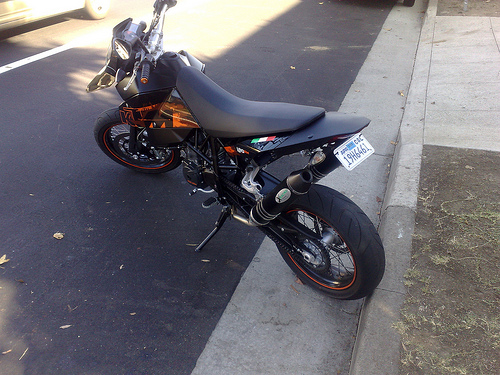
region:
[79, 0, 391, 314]
Motorcycle parked on the street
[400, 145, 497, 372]
Dead grass and dirt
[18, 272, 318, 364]
Concrete and asphalt street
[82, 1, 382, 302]
Motorcycle made by KTM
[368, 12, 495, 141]
Driveway entrance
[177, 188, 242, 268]
Motorcycle kickstand that's down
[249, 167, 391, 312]
Slick road tires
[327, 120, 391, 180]
Motorcycle license plate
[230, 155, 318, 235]
Muffler on the side of a motorcycle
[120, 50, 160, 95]
Clutch and hand grip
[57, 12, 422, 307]
the bike is black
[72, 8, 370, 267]
the bike is black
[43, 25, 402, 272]
the bike is black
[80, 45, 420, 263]
the bike is black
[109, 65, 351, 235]
the bike is black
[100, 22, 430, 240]
the bike is black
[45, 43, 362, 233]
the bike is black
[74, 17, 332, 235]
the bike is black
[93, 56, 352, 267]
the bike is black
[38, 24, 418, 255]
the bike is black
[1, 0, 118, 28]
car parked in background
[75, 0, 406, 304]
motorcycle parked on street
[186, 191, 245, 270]
kickstand is down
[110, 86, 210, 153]
design on bike is orange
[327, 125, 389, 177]
license plate 19h6461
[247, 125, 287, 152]
flag sticker is from Italy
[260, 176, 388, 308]
stripe on rim is orange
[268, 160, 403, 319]
tire is against curb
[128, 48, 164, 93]
handlebar tip is orange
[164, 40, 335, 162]
seat is black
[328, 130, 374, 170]
License plate on back of motorcycle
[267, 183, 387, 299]
Back wheel of motorcycle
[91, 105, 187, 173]
Front wheel of motorcycle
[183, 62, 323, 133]
Black seat of motorcycle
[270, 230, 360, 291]
Red strip on back wheel of motorcycle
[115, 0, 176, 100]
Handlebars of motorcycle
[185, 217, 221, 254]
Kickstand of motorcycle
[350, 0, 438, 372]
Curb motorcycle is parked next to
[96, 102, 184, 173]
Red strip on front wheet of motorcycle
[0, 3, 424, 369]
Parking pavement that motorcycle is parked on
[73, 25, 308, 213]
the bike is black